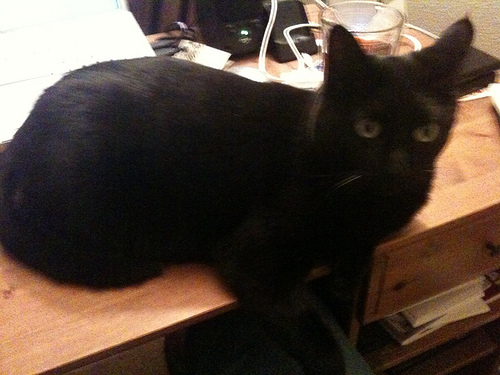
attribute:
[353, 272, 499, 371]
shelving — open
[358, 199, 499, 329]
drawer — pull-out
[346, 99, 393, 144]
eye — cat's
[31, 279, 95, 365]
table — brown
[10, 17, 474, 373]
cat — black , out of focus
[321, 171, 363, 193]
whiskers — white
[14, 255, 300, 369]
brown — color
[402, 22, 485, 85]
ear — cat's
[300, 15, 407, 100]
ear — cat's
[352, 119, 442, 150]
eyes — gold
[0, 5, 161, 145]
laptop screen — fuzzily visible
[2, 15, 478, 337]
cat — black 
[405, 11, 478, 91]
ear — cat's